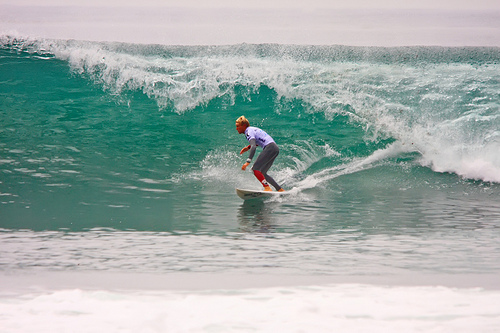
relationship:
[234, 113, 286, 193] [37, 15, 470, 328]
man on beach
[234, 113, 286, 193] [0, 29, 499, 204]
man on gaint wave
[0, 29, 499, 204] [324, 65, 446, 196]
gaint wave on ocean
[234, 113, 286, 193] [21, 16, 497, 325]
man out in sunshine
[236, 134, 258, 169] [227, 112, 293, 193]
arms of surfer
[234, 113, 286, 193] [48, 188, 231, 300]
man in ocean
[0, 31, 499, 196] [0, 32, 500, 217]
bubbles behind wave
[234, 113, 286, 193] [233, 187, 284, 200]
man on board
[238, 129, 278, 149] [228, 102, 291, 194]
shirt on surfer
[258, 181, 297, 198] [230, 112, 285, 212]
feet of surfer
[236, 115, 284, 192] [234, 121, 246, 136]
girl has face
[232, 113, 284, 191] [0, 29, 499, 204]
man surfs gaint wave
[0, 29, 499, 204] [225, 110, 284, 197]
gaint wave by surfer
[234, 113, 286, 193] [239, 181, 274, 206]
man riding surfboard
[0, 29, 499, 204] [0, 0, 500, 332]
gaint wave in ocean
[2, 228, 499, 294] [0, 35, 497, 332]
bubbles on water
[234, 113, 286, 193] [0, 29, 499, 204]
man rides gaint wave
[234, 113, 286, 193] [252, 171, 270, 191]
man wears cord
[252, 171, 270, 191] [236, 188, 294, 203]
cord for board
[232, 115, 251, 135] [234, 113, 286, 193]
head of man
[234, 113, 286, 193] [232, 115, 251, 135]
man has head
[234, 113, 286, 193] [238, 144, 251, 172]
man has hands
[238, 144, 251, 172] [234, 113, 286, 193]
hands of man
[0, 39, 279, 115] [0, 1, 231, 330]
gaint wave in ocean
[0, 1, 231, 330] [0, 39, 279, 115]
ocean has gaint wave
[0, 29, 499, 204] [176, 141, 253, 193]
gaint wave has wave mist